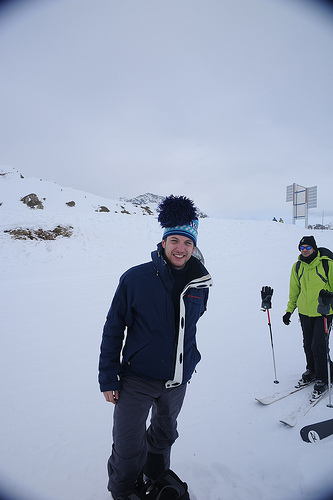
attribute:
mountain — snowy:
[123, 193, 208, 217]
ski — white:
[252, 381, 307, 405]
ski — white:
[278, 382, 332, 428]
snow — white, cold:
[1, 169, 332, 498]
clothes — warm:
[96, 241, 214, 488]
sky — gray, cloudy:
[1, 0, 330, 213]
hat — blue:
[160, 213, 198, 247]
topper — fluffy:
[157, 193, 198, 226]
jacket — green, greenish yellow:
[284, 246, 332, 319]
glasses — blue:
[298, 243, 313, 251]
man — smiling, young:
[97, 194, 213, 498]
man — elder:
[282, 234, 332, 392]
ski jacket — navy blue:
[98, 240, 211, 390]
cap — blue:
[157, 194, 199, 243]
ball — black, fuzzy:
[157, 195, 196, 228]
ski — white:
[254, 382, 313, 405]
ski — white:
[277, 388, 327, 427]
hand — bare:
[101, 390, 119, 403]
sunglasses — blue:
[299, 244, 312, 250]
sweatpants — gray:
[107, 375, 186, 499]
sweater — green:
[285, 246, 332, 316]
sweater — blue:
[97, 243, 213, 391]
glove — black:
[259, 285, 274, 312]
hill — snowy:
[1, 168, 332, 499]